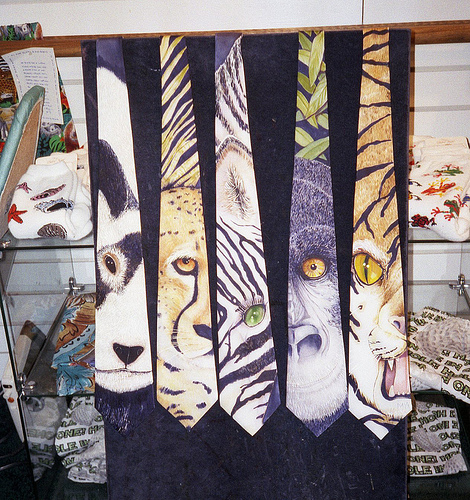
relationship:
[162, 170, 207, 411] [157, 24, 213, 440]
cheetah on tie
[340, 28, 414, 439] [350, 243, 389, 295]
tiger has eye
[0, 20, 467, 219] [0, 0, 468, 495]
bar over wall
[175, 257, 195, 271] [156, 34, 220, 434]
eye on tie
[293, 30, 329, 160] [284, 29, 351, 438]
leaves on tie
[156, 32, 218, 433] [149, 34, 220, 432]
cheetah on tie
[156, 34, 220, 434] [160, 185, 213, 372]
tie featuring cheetah face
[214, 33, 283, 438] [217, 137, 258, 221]
tie with ear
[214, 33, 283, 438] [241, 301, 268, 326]
tie with eye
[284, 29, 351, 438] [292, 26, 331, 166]
tie with leaf pattern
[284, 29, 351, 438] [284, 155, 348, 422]
tie with face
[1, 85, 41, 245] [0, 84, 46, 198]
ironing board with cover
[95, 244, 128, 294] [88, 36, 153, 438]
eye on tie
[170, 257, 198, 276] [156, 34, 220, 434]
eye on tie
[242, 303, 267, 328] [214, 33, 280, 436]
eye on tie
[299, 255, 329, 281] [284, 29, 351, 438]
eye on tie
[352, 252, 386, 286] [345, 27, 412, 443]
eye on tie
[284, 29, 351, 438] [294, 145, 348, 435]
tie projects gorilla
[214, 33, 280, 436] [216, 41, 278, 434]
tie projects zebra image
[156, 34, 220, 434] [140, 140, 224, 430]
tie projects leopard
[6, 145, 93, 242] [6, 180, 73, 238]
blanket has shells print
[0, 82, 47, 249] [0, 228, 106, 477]
ironing board leaning against shelving unit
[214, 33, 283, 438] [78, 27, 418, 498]
tie leaning hanging on board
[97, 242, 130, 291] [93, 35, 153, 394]
eye on tie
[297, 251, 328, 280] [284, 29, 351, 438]
eye on tie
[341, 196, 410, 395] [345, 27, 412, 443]
image on tie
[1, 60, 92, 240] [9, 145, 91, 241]
blanket with sea shells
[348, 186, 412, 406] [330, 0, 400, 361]
tiger face on tie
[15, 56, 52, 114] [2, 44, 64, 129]
writing on paper